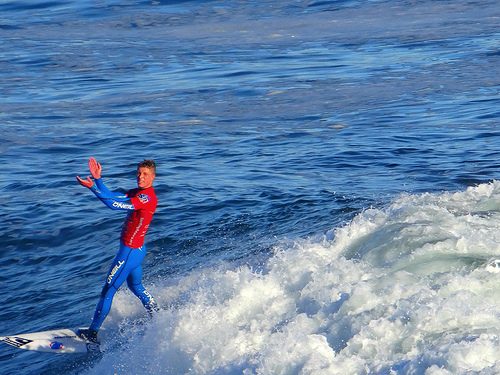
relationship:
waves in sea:
[199, 171, 456, 336] [2, 0, 497, 374]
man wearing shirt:
[66, 139, 193, 299] [82, 172, 162, 255]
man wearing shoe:
[66, 139, 193, 299] [73, 328, 98, 344]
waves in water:
[360, 91, 446, 145] [2, 172, 497, 375]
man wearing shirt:
[66, 139, 193, 299] [120, 174, 172, 249]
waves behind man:
[199, 171, 456, 336] [84, 143, 191, 345]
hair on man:
[134, 159, 157, 191] [66, 139, 193, 299]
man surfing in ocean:
[66, 139, 193, 299] [1, 5, 495, 373]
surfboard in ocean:
[0, 326, 119, 355] [1, 5, 495, 373]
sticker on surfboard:
[46, 339, 65, 349] [1, 318, 131, 353]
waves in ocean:
[199, 171, 456, 336] [1, 5, 495, 373]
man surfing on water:
[66, 139, 193, 299] [187, 221, 326, 311]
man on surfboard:
[66, 139, 193, 299] [9, 323, 104, 363]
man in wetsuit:
[66, 139, 193, 299] [96, 182, 162, 259]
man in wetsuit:
[66, 139, 193, 299] [72, 180, 168, 330]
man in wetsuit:
[66, 139, 193, 299] [85, 175, 160, 336]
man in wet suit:
[66, 139, 193, 299] [89, 177, 157, 332]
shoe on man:
[73, 321, 102, 345] [56, 133, 168, 345]